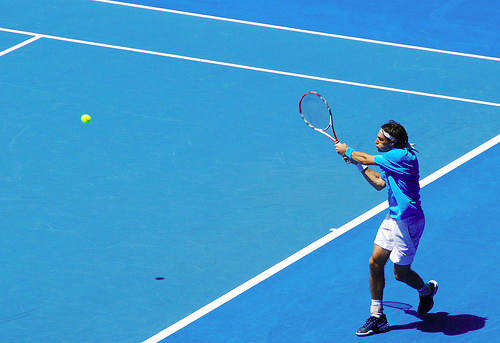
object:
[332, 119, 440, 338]
tennis player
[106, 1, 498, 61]
line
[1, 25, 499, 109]
line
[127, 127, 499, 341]
line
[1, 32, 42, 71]
line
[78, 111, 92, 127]
tennis ball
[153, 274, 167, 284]
shadow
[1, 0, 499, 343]
court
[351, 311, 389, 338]
shoe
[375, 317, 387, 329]
nike emblem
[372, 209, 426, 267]
shorts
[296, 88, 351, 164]
tennis racket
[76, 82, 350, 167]
tennis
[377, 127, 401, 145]
headband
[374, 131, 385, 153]
face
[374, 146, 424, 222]
shirt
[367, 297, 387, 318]
socks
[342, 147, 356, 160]
sweat band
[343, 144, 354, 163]
wrist